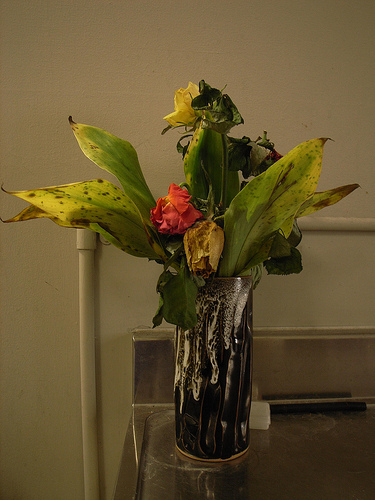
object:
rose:
[152, 183, 207, 234]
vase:
[174, 273, 252, 463]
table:
[112, 326, 375, 500]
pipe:
[76, 227, 102, 500]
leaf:
[220, 135, 332, 275]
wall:
[2, 2, 374, 79]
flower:
[2, 79, 360, 330]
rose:
[183, 219, 225, 275]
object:
[270, 401, 368, 414]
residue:
[272, 412, 335, 441]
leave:
[151, 273, 200, 328]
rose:
[163, 82, 200, 129]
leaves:
[224, 132, 270, 172]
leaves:
[298, 180, 360, 224]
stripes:
[196, 317, 212, 455]